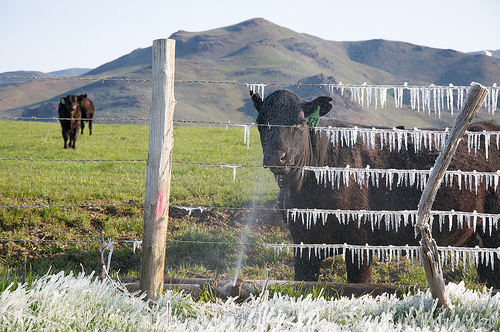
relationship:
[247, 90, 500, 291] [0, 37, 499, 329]
cow behind fence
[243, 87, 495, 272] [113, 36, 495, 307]
cow behind fence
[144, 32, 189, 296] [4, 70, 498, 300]
pole holding up fence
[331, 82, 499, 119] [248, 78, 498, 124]
icicles hanging from wire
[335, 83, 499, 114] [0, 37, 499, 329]
icicles hanging from fence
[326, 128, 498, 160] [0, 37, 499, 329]
icicles hanging from fence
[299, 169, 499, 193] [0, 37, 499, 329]
icicles hanging from fence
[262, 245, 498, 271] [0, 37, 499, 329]
icicles hanging from fence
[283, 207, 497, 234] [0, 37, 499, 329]
icicles hanging from fence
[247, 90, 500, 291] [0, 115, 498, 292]
cow in field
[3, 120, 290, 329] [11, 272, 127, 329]
field with grass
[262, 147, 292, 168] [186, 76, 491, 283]
nose of cow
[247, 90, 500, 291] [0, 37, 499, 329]
cow near fence